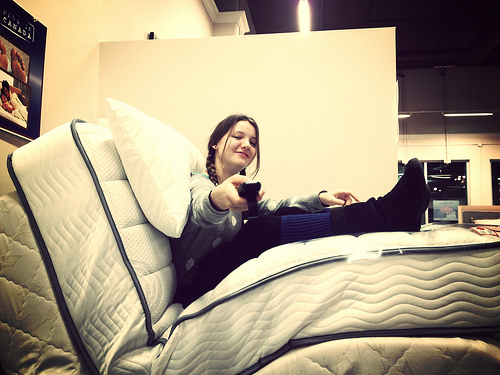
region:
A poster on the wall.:
[3, 5, 55, 142]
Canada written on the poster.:
[3, 13, 40, 43]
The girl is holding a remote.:
[231, 173, 264, 218]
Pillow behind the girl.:
[109, 100, 211, 232]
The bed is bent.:
[15, 131, 495, 373]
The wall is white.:
[91, 39, 395, 131]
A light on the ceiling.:
[286, 0, 321, 35]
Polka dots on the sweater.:
[170, 205, 243, 262]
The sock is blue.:
[276, 210, 338, 240]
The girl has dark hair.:
[200, 115, 265, 186]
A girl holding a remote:
[210, 113, 260, 209]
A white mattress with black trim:
[20, 120, 200, 345]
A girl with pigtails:
[200, 100, 272, 175]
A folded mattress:
[21, 121, 226, 358]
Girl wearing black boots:
[335, 157, 440, 242]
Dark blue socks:
[280, 206, 325, 236]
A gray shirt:
[195, 176, 220, 246]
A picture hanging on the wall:
[5, 0, 55, 132]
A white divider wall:
[100, 30, 400, 102]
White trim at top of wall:
[200, 1, 250, 31]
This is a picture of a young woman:
[181, 105, 373, 268]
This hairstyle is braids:
[206, 95, 251, 209]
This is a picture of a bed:
[30, 84, 421, 349]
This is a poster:
[16, 48, 63, 143]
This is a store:
[133, 99, 499, 318]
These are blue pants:
[222, 200, 324, 256]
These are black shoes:
[368, 133, 495, 310]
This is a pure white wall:
[126, 43, 289, 125]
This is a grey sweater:
[192, 214, 238, 243]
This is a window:
[435, 153, 487, 206]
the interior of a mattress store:
[0, 0, 499, 374]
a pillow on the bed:
[105, 96, 207, 238]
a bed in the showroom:
[0, 118, 499, 374]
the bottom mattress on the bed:
[0, 189, 499, 374]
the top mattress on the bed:
[5, 117, 498, 374]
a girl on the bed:
[171, 113, 431, 308]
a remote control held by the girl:
[236, 180, 261, 197]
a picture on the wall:
[0, 0, 47, 142]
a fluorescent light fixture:
[440, 109, 492, 116]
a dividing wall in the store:
[97, 25, 396, 222]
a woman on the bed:
[16, 113, 431, 367]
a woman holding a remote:
[170, 114, 430, 309]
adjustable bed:
[3, 120, 489, 374]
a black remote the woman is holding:
[241, 179, 262, 196]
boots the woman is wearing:
[346, 158, 431, 233]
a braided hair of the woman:
[206, 153, 218, 183]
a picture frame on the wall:
[1, 48, 44, 138]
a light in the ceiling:
[296, 1, 312, 31]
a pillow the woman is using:
[108, 95, 188, 237]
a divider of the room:
[108, 25, 398, 192]